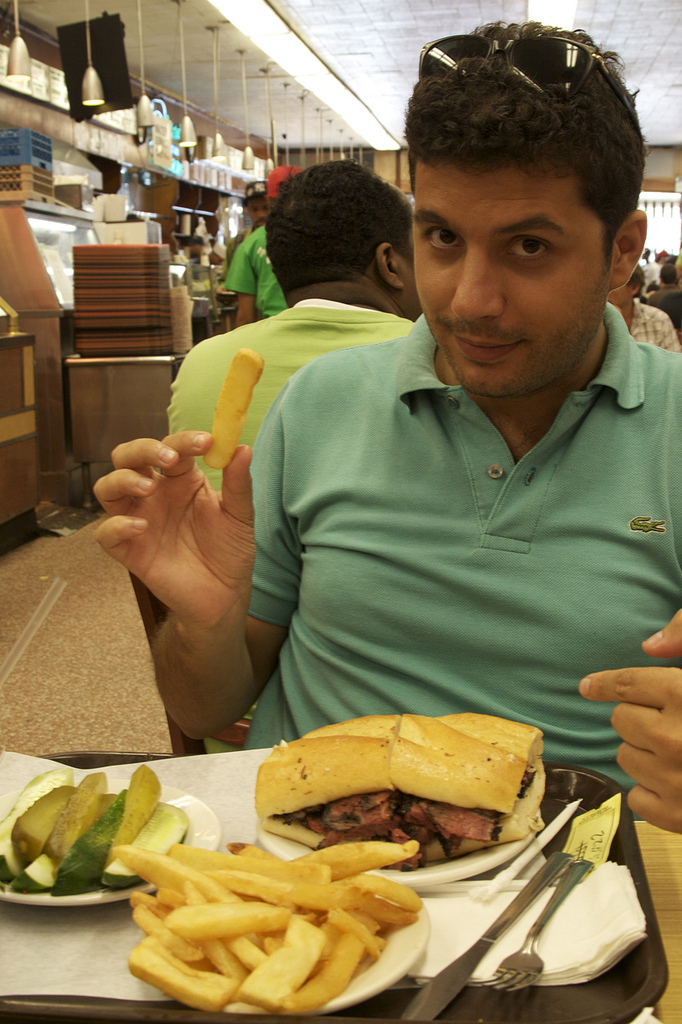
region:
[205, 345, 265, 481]
the french fry in the man's hand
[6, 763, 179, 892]
the sliced pickles on the man's plate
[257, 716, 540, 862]
the sandwich sitting on another plate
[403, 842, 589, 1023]
the silverware sitting on the tray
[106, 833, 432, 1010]
the plate filled with french fries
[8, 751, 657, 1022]
the tray sitting on the table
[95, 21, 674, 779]
the man sitting next to the table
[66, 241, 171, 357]
a stack of trays sitting next to the counter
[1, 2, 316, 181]
a row of lights hanging from the roof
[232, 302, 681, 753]
the blue shirt the man is wearing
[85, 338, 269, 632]
fried potato in right hand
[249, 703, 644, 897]
sandwich on brown tray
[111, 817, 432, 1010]
fried potatos on white plate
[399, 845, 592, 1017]
silver knife and fork on paper napkins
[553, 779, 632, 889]
yellow meal ticket on brown tray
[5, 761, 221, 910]
green pickles on white plate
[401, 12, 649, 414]
black plastic sunglasses in mans hair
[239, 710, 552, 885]
roast beef sandwich on white plate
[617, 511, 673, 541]
green alligator on shirt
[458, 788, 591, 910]
plastic straw in white paper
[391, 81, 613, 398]
the head of a man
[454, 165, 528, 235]
the forhead of a man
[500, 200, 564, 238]
the eyebrows of a man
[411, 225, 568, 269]
the eyes of a man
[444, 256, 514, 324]
the nose of a man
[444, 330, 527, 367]
the lips of a man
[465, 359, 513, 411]
the chin of a man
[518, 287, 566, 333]
the cheek of a man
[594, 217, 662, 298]
the ear of a man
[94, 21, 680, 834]
Man pointing at his beef sandwich.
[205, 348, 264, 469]
French fry wedge held by man.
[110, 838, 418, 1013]
Plate of french fries in front of the sandwich.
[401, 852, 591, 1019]
Fork and knife silverware on the plate.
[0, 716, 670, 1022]
Dark brown tray of food in front of man.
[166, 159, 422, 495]
Man in green behind man in blue.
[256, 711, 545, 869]
Golden brown, roast beef sandwich.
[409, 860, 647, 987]
Napkins underneath the utensils.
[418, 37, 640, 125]
Black glasses on the man with a fry's head.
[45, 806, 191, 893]
a view of pieces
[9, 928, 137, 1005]
a view of table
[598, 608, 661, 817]
fingers of the person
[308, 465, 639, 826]
a view of shirt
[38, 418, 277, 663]
hand of the person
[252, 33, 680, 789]
a man in a green shirt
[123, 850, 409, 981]
french fries on a plate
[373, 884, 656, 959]
napkins on a tray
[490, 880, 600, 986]
a fork on a napkin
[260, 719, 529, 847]
a sandwich on a plate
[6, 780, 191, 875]
pickles on a plate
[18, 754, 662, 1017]
a black tray on a table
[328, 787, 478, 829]
meat on a sandwich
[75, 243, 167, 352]
a stack of trays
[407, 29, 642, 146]
sunglasses worn by human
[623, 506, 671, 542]
alligator attached to shirt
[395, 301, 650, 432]
collar attached to shirt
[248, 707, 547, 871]
sandwich cut in half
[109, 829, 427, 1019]
frenchfries rest on white plate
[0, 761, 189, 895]
pickles sit on white plate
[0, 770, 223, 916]
round white plate underneath pickle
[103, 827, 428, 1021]
white plate underneath fries